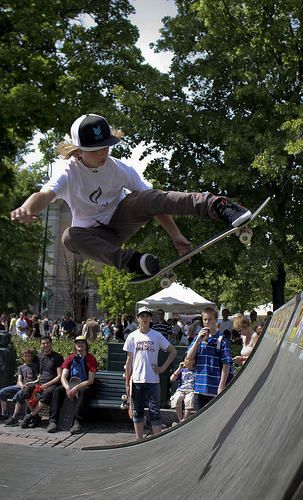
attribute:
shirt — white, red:
[43, 158, 148, 230]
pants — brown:
[63, 188, 223, 269]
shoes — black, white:
[134, 200, 248, 273]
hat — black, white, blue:
[69, 112, 120, 152]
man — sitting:
[170, 353, 198, 424]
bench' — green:
[78, 371, 173, 407]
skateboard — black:
[127, 197, 272, 285]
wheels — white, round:
[160, 231, 252, 291]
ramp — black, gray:
[4, 295, 301, 498]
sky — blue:
[24, 0, 207, 189]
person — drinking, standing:
[122, 306, 178, 440]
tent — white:
[137, 280, 221, 320]